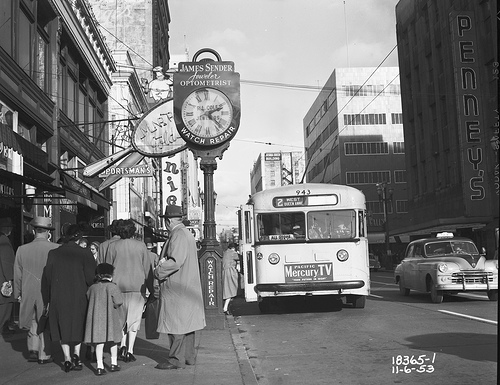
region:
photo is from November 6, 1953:
[367, 339, 468, 381]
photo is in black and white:
[1, 2, 496, 382]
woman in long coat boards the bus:
[212, 171, 379, 309]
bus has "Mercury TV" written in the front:
[243, 172, 380, 317]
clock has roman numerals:
[163, 45, 255, 167]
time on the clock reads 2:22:
[164, 45, 247, 169]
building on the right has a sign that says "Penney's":
[396, 3, 498, 273]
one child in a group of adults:
[55, 215, 136, 373]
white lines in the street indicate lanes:
[344, 271, 498, 353]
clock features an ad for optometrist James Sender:
[169, 45, 251, 155]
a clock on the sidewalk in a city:
[172, 44, 258, 374]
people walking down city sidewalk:
[11, 185, 206, 383]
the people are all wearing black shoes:
[21, 345, 137, 377]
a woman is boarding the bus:
[221, 180, 373, 322]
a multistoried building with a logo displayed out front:
[393, 0, 499, 273]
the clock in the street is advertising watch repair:
[174, 47, 243, 330]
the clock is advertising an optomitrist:
[174, 59, 240, 135]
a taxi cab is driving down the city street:
[392, 228, 499, 321]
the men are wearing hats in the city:
[27, 202, 188, 233]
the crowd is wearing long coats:
[12, 217, 209, 370]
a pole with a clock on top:
[171, 47, 250, 333]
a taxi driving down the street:
[396, 230, 496, 305]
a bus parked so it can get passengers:
[239, 185, 364, 305]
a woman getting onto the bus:
[216, 240, 245, 318]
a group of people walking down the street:
[16, 215, 209, 379]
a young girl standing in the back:
[81, 260, 131, 372]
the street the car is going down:
[242, 257, 493, 384]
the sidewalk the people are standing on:
[7, 319, 254, 384]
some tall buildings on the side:
[292, 4, 497, 231]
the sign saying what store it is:
[450, 1, 494, 235]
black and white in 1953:
[5, 2, 493, 377]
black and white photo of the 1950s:
[3, 13, 497, 379]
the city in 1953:
[2, 4, 498, 381]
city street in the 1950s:
[3, 3, 498, 381]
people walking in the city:
[2, 194, 224, 381]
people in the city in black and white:
[4, 193, 216, 375]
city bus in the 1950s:
[210, 181, 384, 321]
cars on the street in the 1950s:
[216, 151, 498, 353]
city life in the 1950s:
[2, 5, 498, 381]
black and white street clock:
[164, 42, 250, 344]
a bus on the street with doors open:
[226, 169, 373, 328]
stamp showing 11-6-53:
[384, 344, 446, 380]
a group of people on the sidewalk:
[4, 205, 231, 380]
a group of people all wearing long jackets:
[21, 211, 206, 363]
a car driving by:
[384, 215, 496, 308]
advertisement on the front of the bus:
[276, 255, 348, 282]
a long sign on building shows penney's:
[427, 7, 494, 241]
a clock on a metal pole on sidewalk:
[174, 40, 240, 331]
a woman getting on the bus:
[209, 211, 266, 328]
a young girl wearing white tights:
[81, 248, 137, 376]